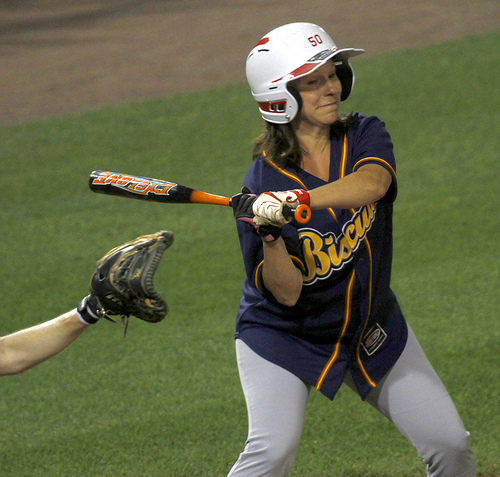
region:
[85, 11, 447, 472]
a woman swinging a bat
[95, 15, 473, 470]
a woman playing softball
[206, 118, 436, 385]
a blue and gold Biscuits jersey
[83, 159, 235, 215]
an orange and black softball bat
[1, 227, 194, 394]
a hand holding a catcher's mitt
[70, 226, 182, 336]
a black leather catcher's glove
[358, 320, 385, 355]
the label on a jersey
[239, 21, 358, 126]
a white and red batter's helmet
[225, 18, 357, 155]
a woman wearing a batter's helmet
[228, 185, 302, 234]
a pair of batter's gloves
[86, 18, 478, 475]
person is playing baseball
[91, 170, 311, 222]
the bat is orange and black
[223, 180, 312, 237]
player has on unmatched gloves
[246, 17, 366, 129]
helmet is white and red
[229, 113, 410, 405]
player jersey is navy and yellow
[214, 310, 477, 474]
player is wearing white baseball pants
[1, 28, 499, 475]
the grass is green and manicured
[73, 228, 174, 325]
catchers mitt is black and tan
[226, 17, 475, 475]
player is the batter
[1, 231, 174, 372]
catchers hand beside the batter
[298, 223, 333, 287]
yellow letter on shirt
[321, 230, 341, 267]
yellow letter on shirt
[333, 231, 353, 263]
yellow letter on shirt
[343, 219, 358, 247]
yellow letter on shirt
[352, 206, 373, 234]
yellow letter on shirt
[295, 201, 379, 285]
yellow letters on shirt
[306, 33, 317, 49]
red number on helmet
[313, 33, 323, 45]
red number on helmet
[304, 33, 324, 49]
red numbers on helmet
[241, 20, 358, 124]
white colored batting helmet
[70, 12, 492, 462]
a woman playing softball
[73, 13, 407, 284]
a women swinging a bat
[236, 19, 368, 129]
a woman wearing a batter's helmet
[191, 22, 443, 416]
a woman wearing a softball jersey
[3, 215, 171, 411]
an arm holding a catcher's mitt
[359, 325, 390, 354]
the label on a jersey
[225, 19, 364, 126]
a red and white batter's helmet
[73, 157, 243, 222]
an orange and black softball bat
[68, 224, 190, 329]
a black leather catcher's mitt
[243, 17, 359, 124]
A white baseball helmet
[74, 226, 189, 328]
An open baseball glove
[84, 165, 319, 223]
Orange and black baseball bat being swung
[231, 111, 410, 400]
Blue and yellow baseball jersey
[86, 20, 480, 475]
Woman swinging a baseball bat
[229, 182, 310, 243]
Baseball player wearing mismatched gloves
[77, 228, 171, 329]
Black catcher's mitt stretched open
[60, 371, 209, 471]
Freshly cut, green grass in a baseball park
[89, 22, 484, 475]
A woman swinging a baseball bat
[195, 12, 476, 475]
batter holding a softball bat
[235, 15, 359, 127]
batter wearing batter helmet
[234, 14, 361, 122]
batters helmet is white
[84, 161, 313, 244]
batter holding softball bat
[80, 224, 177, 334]
gloved hand ready to catch ball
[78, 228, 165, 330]
glove on hand is black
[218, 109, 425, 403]
woman wearing blue jersey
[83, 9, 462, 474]
A woman swinging a baseball bat.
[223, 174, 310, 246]
Batting gloves.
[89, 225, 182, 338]
A black and brown baseball glove.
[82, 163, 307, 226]
An orange and black baseball bat.